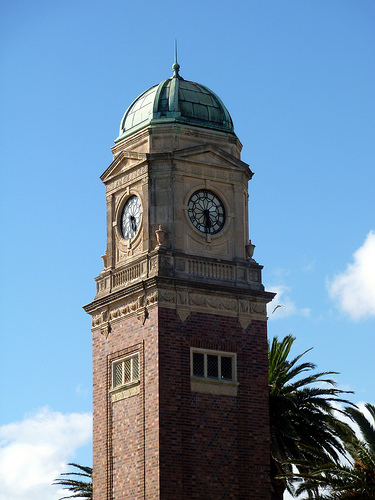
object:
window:
[218, 352, 239, 383]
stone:
[235, 247, 245, 258]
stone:
[234, 229, 243, 241]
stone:
[234, 191, 246, 201]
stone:
[235, 217, 244, 228]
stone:
[174, 221, 185, 237]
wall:
[158, 259, 271, 499]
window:
[189, 348, 205, 380]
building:
[83, 35, 276, 498]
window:
[206, 350, 220, 380]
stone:
[152, 176, 171, 192]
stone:
[153, 189, 170, 206]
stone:
[172, 237, 186, 251]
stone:
[151, 133, 172, 153]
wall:
[150, 123, 247, 259]